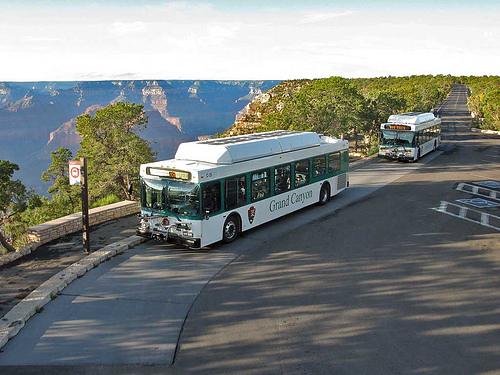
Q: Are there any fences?
A: No, there are no fences.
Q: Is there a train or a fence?
A: No, there are no fences or trains.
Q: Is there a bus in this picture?
A: Yes, there is a bus.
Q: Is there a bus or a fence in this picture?
A: Yes, there is a bus.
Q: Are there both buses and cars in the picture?
A: No, there is a bus but no cars.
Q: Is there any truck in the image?
A: No, there are no trucks.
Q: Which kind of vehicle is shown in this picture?
A: The vehicle is a bus.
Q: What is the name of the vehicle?
A: The vehicle is a bus.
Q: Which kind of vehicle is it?
A: The vehicle is a bus.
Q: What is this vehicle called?
A: That is a bus.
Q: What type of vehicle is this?
A: That is a bus.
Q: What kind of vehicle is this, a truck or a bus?
A: That is a bus.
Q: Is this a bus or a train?
A: This is a bus.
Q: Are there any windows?
A: Yes, there is a window.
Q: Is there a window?
A: Yes, there is a window.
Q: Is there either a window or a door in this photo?
A: Yes, there is a window.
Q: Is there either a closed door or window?
A: Yes, there is a closed window.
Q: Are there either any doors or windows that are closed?
A: Yes, the window is closed.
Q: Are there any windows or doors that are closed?
A: Yes, the window is closed.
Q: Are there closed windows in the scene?
A: Yes, there is a closed window.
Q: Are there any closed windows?
A: Yes, there is a closed window.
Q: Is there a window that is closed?
A: Yes, there is a window that is closed.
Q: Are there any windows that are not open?
A: Yes, there is an closed window.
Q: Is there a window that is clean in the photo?
A: Yes, there is a clean window.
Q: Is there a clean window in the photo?
A: Yes, there is a clean window.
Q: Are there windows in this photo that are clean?
A: Yes, there is a window that is clean.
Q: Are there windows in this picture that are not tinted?
A: Yes, there is a clean window.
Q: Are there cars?
A: No, there are no cars.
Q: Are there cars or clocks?
A: No, there are no cars or clocks.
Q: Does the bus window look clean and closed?
A: Yes, the window is clean and closed.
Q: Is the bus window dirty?
A: No, the window is clean.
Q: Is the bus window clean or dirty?
A: The window is clean.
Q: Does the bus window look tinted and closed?
A: No, the window is closed but clean.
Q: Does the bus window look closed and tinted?
A: No, the window is closed but clean.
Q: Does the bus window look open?
A: No, the window is closed.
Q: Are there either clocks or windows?
A: Yes, there is a window.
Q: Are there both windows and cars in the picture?
A: No, there is a window but no cars.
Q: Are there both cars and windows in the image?
A: No, there is a window but no cars.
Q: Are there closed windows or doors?
A: Yes, there is a closed window.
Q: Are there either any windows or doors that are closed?
A: Yes, the window is closed.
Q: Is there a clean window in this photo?
A: Yes, there is a clean window.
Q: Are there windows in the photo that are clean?
A: Yes, there is a window that is clean.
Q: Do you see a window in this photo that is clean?
A: Yes, there is a window that is clean.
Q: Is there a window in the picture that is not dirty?
A: Yes, there is a clean window.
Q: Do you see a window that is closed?
A: Yes, there is a closed window.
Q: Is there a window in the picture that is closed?
A: Yes, there is a window that is closed.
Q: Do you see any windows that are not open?
A: Yes, there is an closed window.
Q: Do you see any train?
A: No, there are no trains.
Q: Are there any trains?
A: No, there are no trains.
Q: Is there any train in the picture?
A: No, there are no trains.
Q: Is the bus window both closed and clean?
A: Yes, the window is closed and clean.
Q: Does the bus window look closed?
A: Yes, the window is closed.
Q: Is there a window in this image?
A: Yes, there is a window.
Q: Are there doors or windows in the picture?
A: Yes, there is a window.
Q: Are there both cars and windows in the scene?
A: No, there is a window but no cars.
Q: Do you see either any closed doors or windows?
A: Yes, there is a closed window.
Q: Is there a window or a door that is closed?
A: Yes, the window is closed.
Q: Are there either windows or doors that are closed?
A: Yes, the window is closed.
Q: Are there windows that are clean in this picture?
A: Yes, there is a clean window.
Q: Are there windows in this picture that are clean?
A: Yes, there is a window that is clean.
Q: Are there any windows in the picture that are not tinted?
A: Yes, there is a clean window.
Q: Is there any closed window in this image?
A: Yes, there is a closed window.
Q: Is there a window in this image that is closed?
A: Yes, there is a window that is closed.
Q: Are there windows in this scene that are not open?
A: Yes, there is an closed window.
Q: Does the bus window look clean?
A: Yes, the window is clean.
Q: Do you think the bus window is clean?
A: Yes, the window is clean.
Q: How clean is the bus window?
A: The window is clean.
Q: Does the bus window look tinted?
A: No, the window is clean.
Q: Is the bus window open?
A: No, the window is closed.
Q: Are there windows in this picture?
A: Yes, there is a window.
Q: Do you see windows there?
A: Yes, there is a window.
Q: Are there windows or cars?
A: Yes, there is a window.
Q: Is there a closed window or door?
A: Yes, there is a closed window.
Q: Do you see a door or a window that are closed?
A: Yes, the window is closed.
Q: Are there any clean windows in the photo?
A: Yes, there is a clean window.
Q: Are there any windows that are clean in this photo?
A: Yes, there is a clean window.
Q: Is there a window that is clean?
A: Yes, there is a window that is clean.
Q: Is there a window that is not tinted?
A: Yes, there is a clean window.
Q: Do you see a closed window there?
A: Yes, there is a closed window.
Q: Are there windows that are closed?
A: Yes, there is a window that is closed.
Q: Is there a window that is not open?
A: Yes, there is an closed window.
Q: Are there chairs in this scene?
A: No, there are no chairs.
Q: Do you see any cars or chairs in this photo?
A: No, there are no chairs or cars.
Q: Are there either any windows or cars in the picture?
A: Yes, there is a window.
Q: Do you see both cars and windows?
A: No, there is a window but no cars.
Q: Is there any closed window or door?
A: Yes, there is a closed window.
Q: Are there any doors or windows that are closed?
A: Yes, the window is closed.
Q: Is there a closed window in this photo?
A: Yes, there is a closed window.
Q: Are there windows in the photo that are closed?
A: Yes, there is a window that is closed.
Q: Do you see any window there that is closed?
A: Yes, there is a window that is closed.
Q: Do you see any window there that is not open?
A: Yes, there is an closed window.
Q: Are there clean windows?
A: Yes, there is a clean window.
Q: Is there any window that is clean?
A: Yes, there is a window that is clean.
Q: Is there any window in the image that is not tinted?
A: Yes, there is a clean window.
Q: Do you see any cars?
A: No, there are no cars.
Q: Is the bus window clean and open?
A: No, the window is clean but closed.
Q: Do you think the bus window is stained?
A: No, the window is clean.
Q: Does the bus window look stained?
A: No, the window is clean.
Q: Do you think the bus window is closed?
A: Yes, the window is closed.